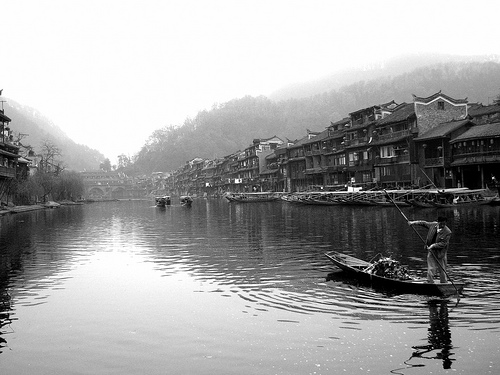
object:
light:
[0, 215, 499, 375]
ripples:
[0, 198, 499, 375]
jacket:
[409, 219, 453, 261]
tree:
[36, 135, 69, 184]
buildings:
[443, 122, 499, 193]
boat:
[317, 250, 466, 297]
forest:
[97, 61, 499, 180]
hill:
[0, 97, 106, 175]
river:
[0, 196, 499, 374]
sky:
[0, 0, 499, 172]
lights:
[202, 140, 357, 189]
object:
[276, 177, 490, 212]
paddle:
[380, 187, 465, 299]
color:
[365, 256, 416, 280]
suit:
[407, 219, 453, 285]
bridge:
[74, 170, 149, 199]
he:
[404, 213, 452, 286]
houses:
[372, 89, 470, 189]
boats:
[179, 194, 194, 209]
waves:
[0, 198, 499, 373]